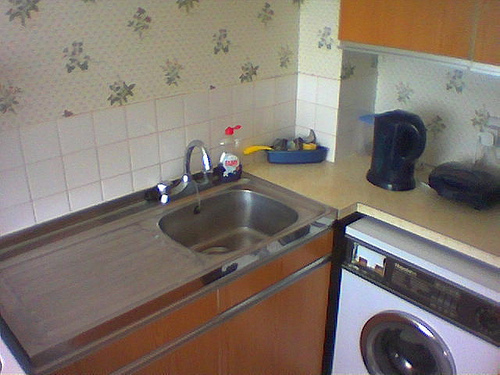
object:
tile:
[0, 200, 37, 236]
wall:
[0, 0, 500, 242]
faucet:
[159, 137, 217, 205]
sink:
[155, 188, 301, 256]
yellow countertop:
[235, 130, 500, 273]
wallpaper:
[0, 0, 296, 125]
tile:
[314, 76, 341, 108]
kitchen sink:
[150, 138, 327, 258]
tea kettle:
[366, 109, 425, 193]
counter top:
[241, 144, 499, 278]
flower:
[63, 42, 95, 74]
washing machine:
[329, 215, 500, 375]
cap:
[223, 123, 241, 136]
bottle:
[211, 123, 245, 186]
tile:
[97, 138, 131, 180]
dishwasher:
[330, 216, 498, 375]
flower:
[158, 54, 185, 87]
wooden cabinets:
[0, 0, 497, 371]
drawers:
[37, 212, 341, 375]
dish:
[261, 141, 332, 165]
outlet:
[469, 110, 498, 150]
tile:
[99, 172, 139, 203]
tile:
[156, 93, 186, 131]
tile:
[122, 102, 159, 139]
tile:
[90, 105, 128, 148]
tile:
[160, 158, 191, 181]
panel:
[346, 245, 391, 285]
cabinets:
[337, 0, 497, 78]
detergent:
[214, 124, 250, 183]